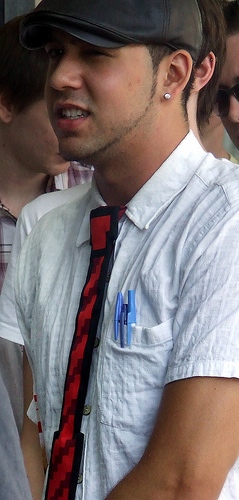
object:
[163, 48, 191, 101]
ear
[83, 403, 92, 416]
button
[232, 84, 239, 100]
sunglasses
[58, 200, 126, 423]
tie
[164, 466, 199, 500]
elbow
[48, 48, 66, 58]
eye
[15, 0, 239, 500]
guy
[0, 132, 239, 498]
shirt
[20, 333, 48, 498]
arm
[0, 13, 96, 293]
lady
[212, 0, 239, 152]
person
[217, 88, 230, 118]
sunglasses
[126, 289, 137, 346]
pen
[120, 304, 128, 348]
pen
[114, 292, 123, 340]
pen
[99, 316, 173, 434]
pocket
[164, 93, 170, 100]
earing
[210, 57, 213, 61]
cartlidge piercing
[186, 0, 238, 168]
person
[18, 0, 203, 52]
cap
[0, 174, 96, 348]
shirt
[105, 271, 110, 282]
button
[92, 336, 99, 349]
button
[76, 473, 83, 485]
button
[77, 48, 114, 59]
eye